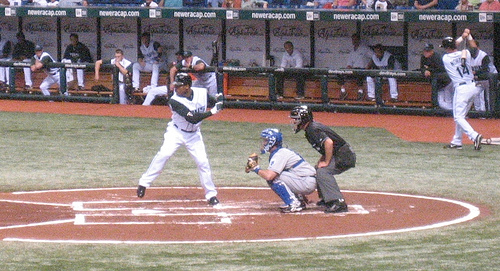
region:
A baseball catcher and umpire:
[249, 105, 366, 227]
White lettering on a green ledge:
[251, 9, 298, 23]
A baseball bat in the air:
[206, 38, 228, 97]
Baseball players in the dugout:
[13, 34, 154, 102]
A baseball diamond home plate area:
[78, 194, 335, 229]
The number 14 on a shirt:
[452, 60, 471, 82]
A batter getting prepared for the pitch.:
[138, 70, 223, 203]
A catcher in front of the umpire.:
[242, 125, 317, 212]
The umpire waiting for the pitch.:
[290, 101, 354, 212]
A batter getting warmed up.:
[437, 24, 486, 149]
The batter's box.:
[68, 195, 225, 212]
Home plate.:
[129, 205, 169, 216]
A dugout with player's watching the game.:
[0, 0, 499, 116]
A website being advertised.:
[245, 7, 297, 22]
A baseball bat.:
[209, 39, 228, 110]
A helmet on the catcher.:
[258, 127, 281, 154]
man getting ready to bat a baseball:
[137, 72, 224, 206]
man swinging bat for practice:
[440, 29, 486, 151]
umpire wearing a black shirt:
[303, 124, 348, 155]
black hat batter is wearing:
[172, 72, 190, 87]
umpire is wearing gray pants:
[315, 155, 340, 202]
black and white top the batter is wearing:
[170, 85, 206, 131]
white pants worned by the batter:
[136, 120, 218, 200]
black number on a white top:
[453, 61, 469, 78]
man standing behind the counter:
[342, 34, 379, 68]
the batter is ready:
[138, 73, 225, 205]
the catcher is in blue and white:
[247, 129, 314, 212]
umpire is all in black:
[291, 103, 356, 213]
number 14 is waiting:
[440, 30, 490, 150]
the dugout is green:
[5, 18, 497, 115]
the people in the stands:
[9, 1, 499, 16]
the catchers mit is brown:
[244, 153, 259, 174]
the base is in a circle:
[18, 185, 479, 237]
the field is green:
[3, 110, 498, 266]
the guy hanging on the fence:
[88, 48, 134, 104]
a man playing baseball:
[154, 65, 215, 170]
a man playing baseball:
[289, 93, 346, 208]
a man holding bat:
[147, 56, 244, 243]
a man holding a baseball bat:
[139, 28, 237, 195]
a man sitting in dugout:
[111, 38, 153, 105]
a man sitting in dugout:
[127, 20, 164, 77]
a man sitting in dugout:
[279, 33, 306, 94]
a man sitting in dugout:
[334, 33, 361, 87]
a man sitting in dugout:
[371, 42, 396, 112]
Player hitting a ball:
[133, 75, 218, 205]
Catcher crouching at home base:
[245, 126, 319, 210]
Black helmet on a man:
[288, 105, 308, 130]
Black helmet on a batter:
[169, 73, 193, 85]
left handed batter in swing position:
[125, 37, 228, 210]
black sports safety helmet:
[167, 68, 194, 93]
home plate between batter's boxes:
[125, 203, 170, 221]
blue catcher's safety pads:
[265, 179, 295, 213]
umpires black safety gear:
[286, 103, 314, 138]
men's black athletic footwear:
[128, 183, 224, 208]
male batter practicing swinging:
[432, 25, 487, 155]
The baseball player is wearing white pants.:
[137, 123, 217, 198]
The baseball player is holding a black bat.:
[206, 37, 222, 107]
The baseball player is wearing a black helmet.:
[171, 68, 196, 86]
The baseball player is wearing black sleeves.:
[171, 100, 213, 125]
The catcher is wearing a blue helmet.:
[254, 123, 281, 153]